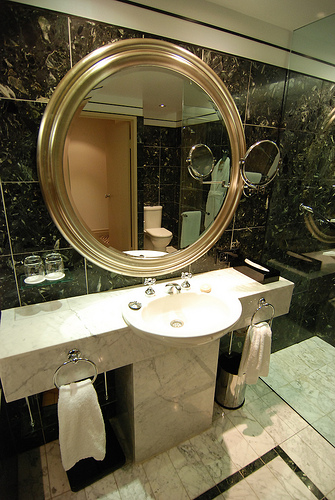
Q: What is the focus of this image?
A: A sink.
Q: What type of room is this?
A: Restroom.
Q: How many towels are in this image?
A: Two.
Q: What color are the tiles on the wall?
A: Black.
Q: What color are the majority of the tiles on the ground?
A: White.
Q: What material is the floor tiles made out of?
A: Marble.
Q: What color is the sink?
A: White.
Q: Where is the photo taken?
A: A bathroom.